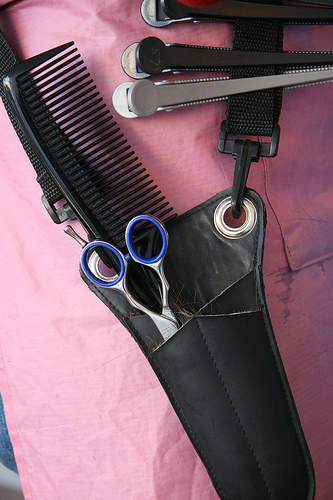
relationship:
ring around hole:
[209, 195, 260, 243] [221, 205, 248, 229]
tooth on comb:
[15, 35, 168, 250] [0, 38, 183, 322]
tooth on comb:
[15, 35, 168, 250] [2, 38, 178, 268]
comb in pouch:
[0, 38, 183, 322] [93, 183, 318, 494]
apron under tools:
[145, 114, 330, 277] [105, 35, 300, 287]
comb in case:
[0, 38, 183, 322] [78, 185, 320, 498]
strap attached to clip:
[213, 5, 295, 140] [218, 120, 279, 214]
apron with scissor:
[0, 0, 332, 499] [63, 213, 179, 343]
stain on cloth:
[272, 266, 304, 317] [269, 151, 330, 339]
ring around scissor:
[127, 216, 166, 263] [63, 213, 179, 343]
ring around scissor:
[79, 240, 125, 286] [63, 213, 179, 343]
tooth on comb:
[15, 35, 168, 250] [1, 41, 169, 251]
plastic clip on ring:
[217, 121, 279, 217] [212, 194, 257, 238]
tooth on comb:
[15, 35, 168, 250] [3, 31, 210, 318]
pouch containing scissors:
[72, 211, 330, 498] [63, 208, 196, 356]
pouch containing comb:
[72, 211, 330, 498] [0, 38, 183, 322]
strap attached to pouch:
[213, 36, 297, 143] [72, 191, 323, 409]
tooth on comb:
[15, 47, 81, 86] [0, 38, 183, 322]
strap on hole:
[213, 5, 295, 140] [200, 189, 261, 245]